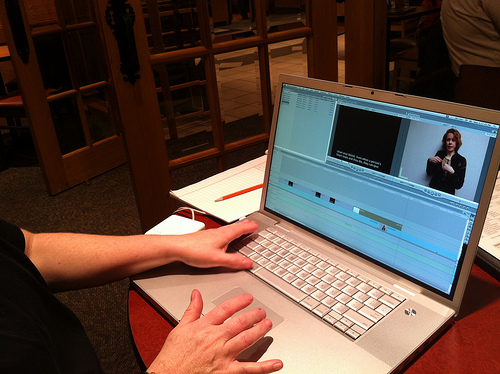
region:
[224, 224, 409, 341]
a silver laptop keyboard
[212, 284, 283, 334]
the touchpad on a keyboard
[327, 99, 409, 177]
a black screen on a laptop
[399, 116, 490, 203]
the image of a woman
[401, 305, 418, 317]
a sticker on the laptop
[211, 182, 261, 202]
a red pencil on paper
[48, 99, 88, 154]
a glass pane in a door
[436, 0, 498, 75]
a white shirt on a man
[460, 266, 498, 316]
a shadow from a laptop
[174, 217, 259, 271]
a man's left hand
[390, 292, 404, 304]
silver button on keyboard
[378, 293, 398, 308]
silver button on keyboard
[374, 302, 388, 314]
silver button on keyboard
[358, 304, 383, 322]
silver button on keyboard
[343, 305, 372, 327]
silver button on keyboard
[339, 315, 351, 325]
silver button on keyboard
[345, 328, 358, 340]
silver button on keyboard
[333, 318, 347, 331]
silver button on keyboard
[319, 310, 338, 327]
silver button on keyboard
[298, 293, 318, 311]
silver button on keyboard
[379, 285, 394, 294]
silver button on keyboard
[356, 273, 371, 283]
silver button on keyboard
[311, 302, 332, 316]
silver button on keyboard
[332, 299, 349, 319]
silver button on keyboard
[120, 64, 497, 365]
silver laptop on red table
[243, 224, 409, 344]
silver laptop keyboard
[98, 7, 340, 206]
wooden door with several pieces of glass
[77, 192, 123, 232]
carpet on floor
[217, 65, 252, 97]
tile on floor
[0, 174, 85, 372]
black t shirt on man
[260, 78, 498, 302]
silver laptop computer screen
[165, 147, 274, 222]
paper and pencil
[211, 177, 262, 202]
pencil on paper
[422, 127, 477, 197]
lady in hallway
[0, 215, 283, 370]
a person sitting in front of a laptop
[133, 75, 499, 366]
a silver laptop on a table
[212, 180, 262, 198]
a red pencil on a stack of papers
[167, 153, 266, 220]
white papers on a table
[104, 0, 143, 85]
black handle on a wooden door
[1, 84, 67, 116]
red cushion on a stuffed chair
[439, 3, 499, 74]
person wearing a white shirt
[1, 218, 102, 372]
person wearing a black shirt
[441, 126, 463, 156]
a woman with red hair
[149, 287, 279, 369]
a hand on a laptop